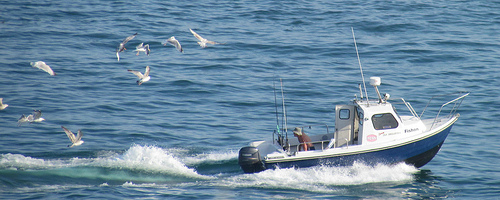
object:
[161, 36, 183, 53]
bird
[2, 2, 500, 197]
water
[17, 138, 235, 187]
wake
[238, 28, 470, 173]
boat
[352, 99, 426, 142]
cabin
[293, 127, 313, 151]
man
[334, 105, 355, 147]
door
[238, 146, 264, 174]
engine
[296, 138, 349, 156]
railing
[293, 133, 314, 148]
shirt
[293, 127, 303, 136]
hat